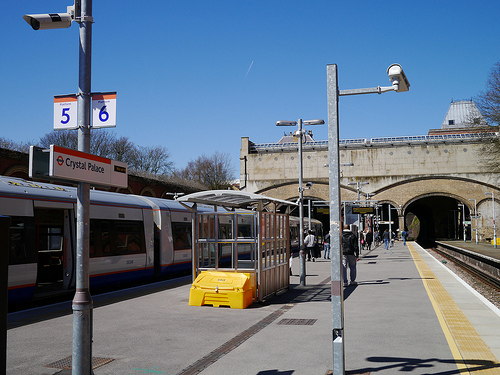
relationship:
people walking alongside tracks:
[353, 222, 413, 252] [418, 224, 498, 320]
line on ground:
[403, 237, 495, 373] [5, 239, 498, 374]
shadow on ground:
[347, 356, 499, 372] [101, 305, 328, 362]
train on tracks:
[0, 172, 324, 316] [0, 271, 193, 323]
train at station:
[0, 172, 324, 316] [32, 51, 497, 369]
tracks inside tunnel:
[419, 240, 497, 300] [402, 189, 472, 244]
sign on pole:
[28, 91, 130, 190] [56, 0, 104, 366]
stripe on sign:
[51, 141, 115, 166] [28, 91, 130, 190]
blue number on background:
[94, 102, 116, 125] [90, 90, 122, 128]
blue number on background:
[55, 97, 72, 130] [49, 92, 81, 133]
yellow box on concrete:
[185, 261, 257, 313] [2, 242, 447, 373]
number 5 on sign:
[59, 106, 71, 125] [28, 91, 130, 190]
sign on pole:
[28, 91, 130, 190] [69, 0, 95, 375]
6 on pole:
[97, 99, 113, 128] [55, 6, 113, 373]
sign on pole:
[28, 91, 130, 190] [55, 6, 113, 373]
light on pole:
[384, 64, 415, 94] [319, 64, 415, 374]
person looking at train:
[303, 229, 323, 262] [1, 142, 335, 285]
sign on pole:
[28, 88, 147, 197] [18, 1, 107, 371]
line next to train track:
[403, 237, 495, 373] [401, 222, 495, 325]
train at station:
[0, 172, 324, 316] [115, 253, 497, 363]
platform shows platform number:
[5, 238, 495, 375] [49, 90, 117, 131]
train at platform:
[0, 172, 324, 316] [5, 238, 495, 375]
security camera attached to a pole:
[384, 60, 414, 93] [319, 57, 350, 369]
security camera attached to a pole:
[18, 6, 77, 33] [70, 2, 97, 374]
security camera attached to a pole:
[290, 129, 317, 141] [293, 126, 310, 289]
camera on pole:
[386, 56, 423, 88] [326, 63, 345, 375]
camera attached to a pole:
[291, 127, 315, 144] [294, 115, 307, 291]